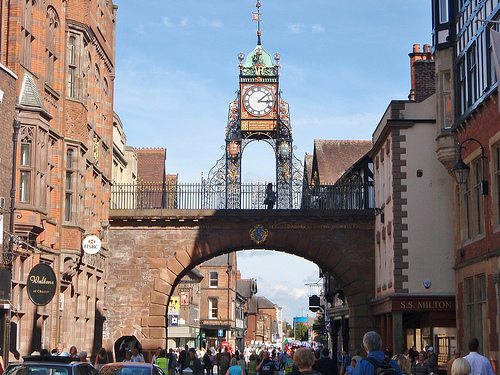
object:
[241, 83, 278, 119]
clock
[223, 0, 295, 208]
tower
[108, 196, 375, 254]
bridge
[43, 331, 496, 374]
people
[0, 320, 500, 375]
street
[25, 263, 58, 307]
sign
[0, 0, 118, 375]
building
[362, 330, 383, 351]
hair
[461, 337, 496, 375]
man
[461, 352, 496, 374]
dress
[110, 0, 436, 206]
sky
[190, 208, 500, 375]
shadow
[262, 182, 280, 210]
person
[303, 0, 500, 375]
buildings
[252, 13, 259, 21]
flag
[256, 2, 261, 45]
pole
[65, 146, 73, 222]
windows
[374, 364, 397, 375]
bag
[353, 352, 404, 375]
shirt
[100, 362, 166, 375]
car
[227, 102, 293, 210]
archway